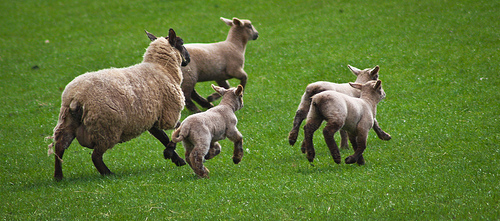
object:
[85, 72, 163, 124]
wool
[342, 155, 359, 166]
hooves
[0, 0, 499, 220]
grass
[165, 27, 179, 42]
ears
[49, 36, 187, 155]
coat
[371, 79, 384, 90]
ears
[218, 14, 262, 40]
head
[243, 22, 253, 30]
eye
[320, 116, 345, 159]
leg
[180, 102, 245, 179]
torso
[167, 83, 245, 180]
animal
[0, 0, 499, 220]
field